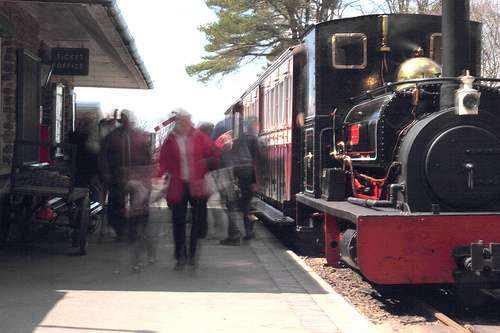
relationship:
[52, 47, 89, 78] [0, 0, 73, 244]
sign for ticket office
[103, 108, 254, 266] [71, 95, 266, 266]
people out of focus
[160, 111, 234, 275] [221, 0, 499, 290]
lady in red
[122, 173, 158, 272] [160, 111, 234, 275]
child holding hand with lady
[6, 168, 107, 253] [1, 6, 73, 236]
bench against wall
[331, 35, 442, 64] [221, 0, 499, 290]
front windows on train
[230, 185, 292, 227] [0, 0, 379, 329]
loading dock for train station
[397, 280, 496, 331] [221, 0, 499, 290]
tracks for train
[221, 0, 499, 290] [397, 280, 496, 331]
train on tracks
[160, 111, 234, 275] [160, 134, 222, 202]
lady wearing red coat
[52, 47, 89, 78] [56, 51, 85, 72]
sign says ticket office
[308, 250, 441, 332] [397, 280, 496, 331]
gravel next to tracks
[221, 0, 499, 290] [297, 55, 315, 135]
train carries passengers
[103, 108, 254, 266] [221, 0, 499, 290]
people walking next to train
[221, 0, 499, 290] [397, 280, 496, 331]
train sitting on tracks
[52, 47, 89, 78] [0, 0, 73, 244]
sign indicating ticket office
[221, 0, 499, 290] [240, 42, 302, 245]
train has passager car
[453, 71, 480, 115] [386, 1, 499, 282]
lantern in front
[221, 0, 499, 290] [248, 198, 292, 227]
train has boarding platform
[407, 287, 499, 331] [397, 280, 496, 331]
set of tracks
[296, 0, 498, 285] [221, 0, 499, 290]
engine of train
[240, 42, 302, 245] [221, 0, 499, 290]
car of train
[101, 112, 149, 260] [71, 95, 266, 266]
person out of focus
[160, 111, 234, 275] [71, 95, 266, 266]
person out of focus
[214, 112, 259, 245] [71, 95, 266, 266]
person out of focus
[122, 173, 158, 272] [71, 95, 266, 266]
person out of focus